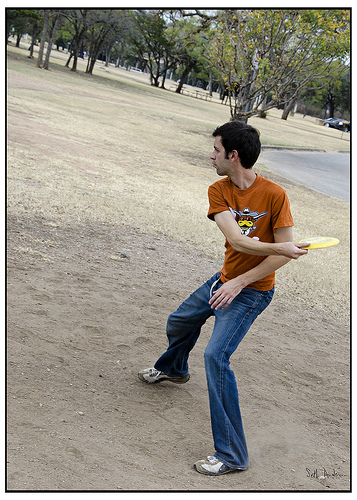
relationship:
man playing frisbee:
[138, 120, 310, 475] [294, 235, 340, 251]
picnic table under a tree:
[192, 87, 214, 101] [189, 35, 225, 97]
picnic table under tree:
[192, 87, 214, 101] [189, 35, 225, 97]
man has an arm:
[138, 120, 310, 475] [213, 209, 281, 261]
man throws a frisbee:
[138, 120, 310, 475] [294, 235, 340, 251]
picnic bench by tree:
[172, 82, 188, 95] [176, 41, 195, 97]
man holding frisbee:
[138, 120, 310, 475] [294, 235, 340, 251]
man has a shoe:
[138, 120, 310, 475] [137, 366, 188, 386]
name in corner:
[306, 465, 349, 483] [300, 453, 351, 493]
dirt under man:
[7, 221, 352, 491] [138, 120, 310, 475]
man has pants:
[138, 120, 310, 475] [154, 272, 275, 470]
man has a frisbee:
[138, 120, 310, 475] [294, 235, 340, 251]